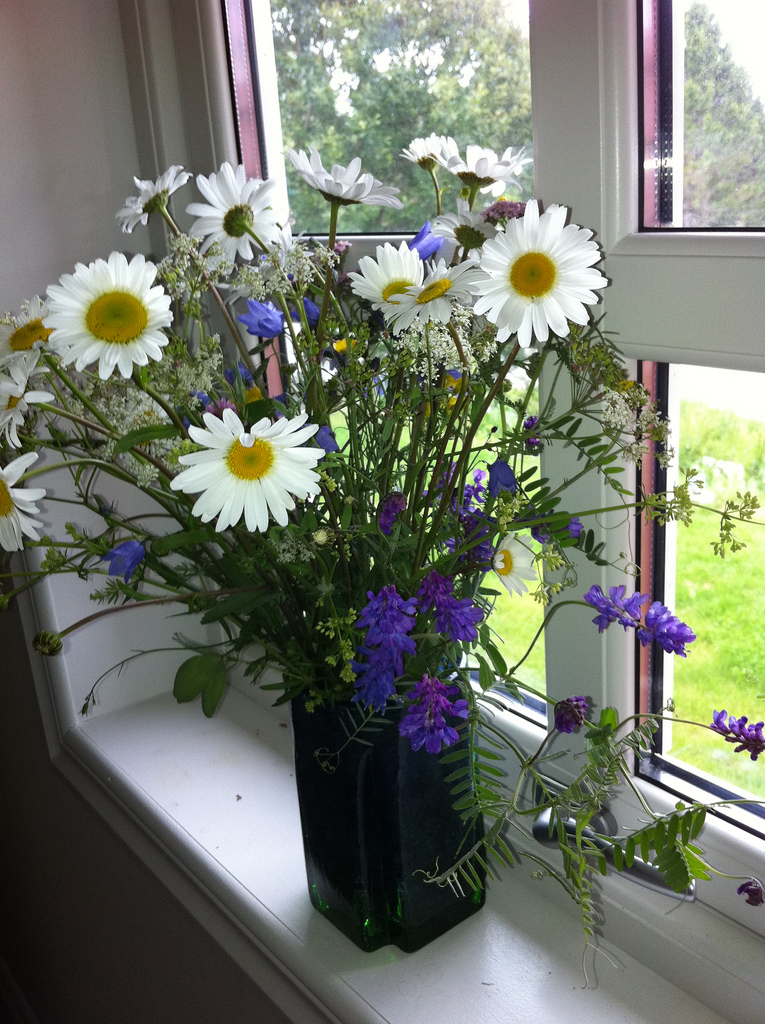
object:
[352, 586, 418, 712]
flower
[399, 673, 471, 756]
flower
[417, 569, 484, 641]
flower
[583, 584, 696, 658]
flower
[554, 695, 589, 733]
flower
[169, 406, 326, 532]
flower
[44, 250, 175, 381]
flower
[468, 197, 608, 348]
flower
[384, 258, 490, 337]
flower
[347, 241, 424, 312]
flower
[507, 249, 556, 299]
flower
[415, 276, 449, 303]
flower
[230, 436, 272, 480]
flower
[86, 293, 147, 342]
flower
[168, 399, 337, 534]
flowers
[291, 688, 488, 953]
vase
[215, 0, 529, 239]
window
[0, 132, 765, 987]
plant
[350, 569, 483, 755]
flowers